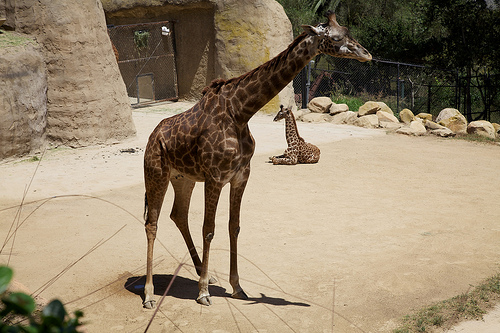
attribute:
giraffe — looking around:
[142, 9, 372, 310]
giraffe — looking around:
[267, 102, 322, 165]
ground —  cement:
[272, 181, 497, 318]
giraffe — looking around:
[146, 38, 365, 305]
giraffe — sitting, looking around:
[271, 105, 321, 164]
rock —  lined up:
[465, 118, 497, 140]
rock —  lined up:
[434, 106, 469, 132]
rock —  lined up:
[397, 108, 415, 124]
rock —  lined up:
[355, 98, 380, 116]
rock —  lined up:
[376, 110, 400, 124]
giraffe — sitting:
[268, 98, 329, 170]